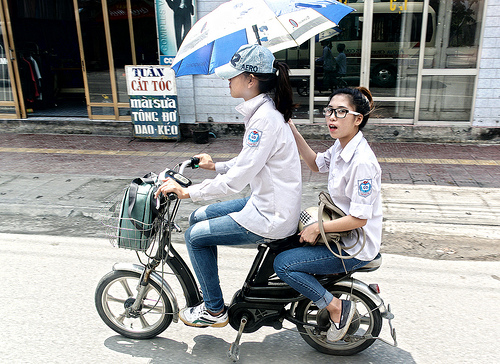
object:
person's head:
[216, 42, 283, 105]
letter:
[131, 108, 158, 121]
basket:
[108, 212, 169, 254]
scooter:
[93, 160, 404, 356]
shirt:
[217, 120, 304, 242]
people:
[269, 81, 390, 348]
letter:
[135, 97, 177, 137]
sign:
[120, 59, 185, 149]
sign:
[130, 66, 183, 135]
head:
[319, 85, 375, 142]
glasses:
[317, 101, 364, 123]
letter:
[153, 65, 165, 77]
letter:
[145, 63, 157, 79]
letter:
[128, 110, 138, 124]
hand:
[275, 212, 343, 264]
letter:
[156, 126, 168, 139]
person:
[164, 41, 307, 330]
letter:
[135, 84, 154, 115]